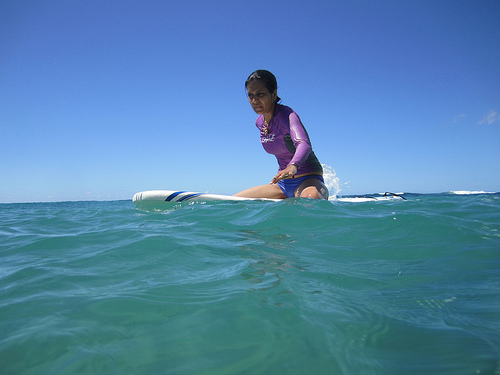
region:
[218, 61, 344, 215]
young woman sitting on surfboard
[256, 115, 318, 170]
young woman wearing purple top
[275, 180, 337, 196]
blue bikini bottoms worn by woman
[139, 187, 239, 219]
blue and white surf board used by woman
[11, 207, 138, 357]
blue green colored water in ocean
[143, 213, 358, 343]
blue green colored water in ocean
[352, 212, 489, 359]
blue green colored water in ocean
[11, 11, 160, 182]
blue sky without clouds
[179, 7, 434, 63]
blue sky without clouds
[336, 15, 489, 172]
blue sky without clouds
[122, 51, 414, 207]
woman riding a surfboard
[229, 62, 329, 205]
woman in a purple shirt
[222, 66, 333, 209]
woman in blue bathing trunks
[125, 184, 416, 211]
white surboard with blue accents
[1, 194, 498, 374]
the water is green colored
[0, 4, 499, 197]
sky is clear and blue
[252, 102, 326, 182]
purple shirt with white writing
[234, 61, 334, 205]
the woman has black hair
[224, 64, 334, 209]
woman with hand extended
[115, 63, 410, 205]
woman sitting on a surfboard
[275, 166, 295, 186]
surfer's hand while paddling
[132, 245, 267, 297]
open ocean water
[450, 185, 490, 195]
wave forming for the surfer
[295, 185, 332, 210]
surfer's knee as she sits on the surfboard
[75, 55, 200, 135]
beautiful blue sky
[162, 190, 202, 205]
stripes on surfboard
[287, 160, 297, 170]
surfer's watch on her wrist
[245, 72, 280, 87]
surfer's hair pulled back into a ponytail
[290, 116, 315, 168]
surfer's paddling arm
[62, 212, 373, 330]
the water is green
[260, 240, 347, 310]
the water is green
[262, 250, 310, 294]
the water is green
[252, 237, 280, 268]
the water is green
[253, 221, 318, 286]
the water is green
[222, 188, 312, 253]
the water is green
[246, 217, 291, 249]
the water is green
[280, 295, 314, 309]
the water is green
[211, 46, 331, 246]
a girl in the water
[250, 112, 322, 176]
the girl has a purple shirt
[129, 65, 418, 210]
she is on a surfboard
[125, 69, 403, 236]
she is floating in water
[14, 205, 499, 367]
the water is very blue green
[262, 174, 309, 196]
she has blue bikini bottoms on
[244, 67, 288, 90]
she has brown hair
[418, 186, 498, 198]
waves crashing in the distance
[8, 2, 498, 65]
the sky is mostly clear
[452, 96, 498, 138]
one small white cloud